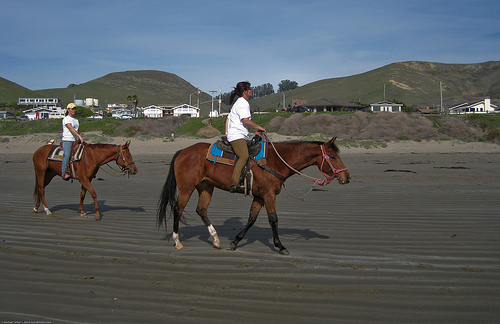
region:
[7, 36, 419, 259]
The horses are brown.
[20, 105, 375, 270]
Two horses next to each other.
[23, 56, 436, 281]
Two people riding horses.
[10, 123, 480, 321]
The horses are walking on the beach.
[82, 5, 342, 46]
The sky is blue.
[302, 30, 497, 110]
The hill is green.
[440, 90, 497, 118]
The house is white.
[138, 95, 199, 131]
A house in the distance.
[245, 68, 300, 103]
Trees on the hillside.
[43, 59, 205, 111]
The hill has green vegetation on it.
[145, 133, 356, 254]
Brown horse in the front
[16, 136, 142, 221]
Brown horse in the back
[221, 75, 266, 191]
Young woman riding horse in the front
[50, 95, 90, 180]
Young woman riding horse in the back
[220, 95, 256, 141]
woman is wearing white tee shirt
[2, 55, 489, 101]
Hillside in the distance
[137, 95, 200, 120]
Two white houses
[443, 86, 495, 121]
One white house in the distance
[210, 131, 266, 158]
Blue saddle blanket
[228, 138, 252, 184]
woman wearing brown pants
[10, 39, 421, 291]
people riding a horse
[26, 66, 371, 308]
people riding a brown horse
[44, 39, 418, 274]
woman riding horses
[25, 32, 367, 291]
women riding brown horses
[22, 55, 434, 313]
horses walking on sand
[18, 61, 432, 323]
horses walking on a beach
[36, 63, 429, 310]
woman riding on sand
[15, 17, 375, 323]
a woman riding on a beach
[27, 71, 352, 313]
women on a saddle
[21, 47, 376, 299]
horses wearing a saddle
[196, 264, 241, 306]
part of a beach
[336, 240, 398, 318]
part of a sand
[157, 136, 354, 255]
a brown horse walking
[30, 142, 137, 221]
a brown horse walking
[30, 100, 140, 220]
a person riding a horse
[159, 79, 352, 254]
a person riding a horse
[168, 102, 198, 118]
a white building in distance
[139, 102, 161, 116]
a white building in distance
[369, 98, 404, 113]
a white building in distance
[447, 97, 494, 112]
a white building in distance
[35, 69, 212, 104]
a distant green hill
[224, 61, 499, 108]
a distant green hill